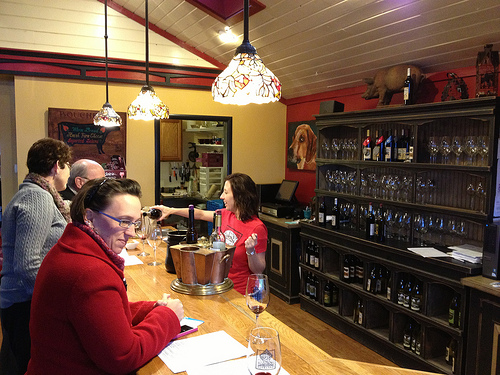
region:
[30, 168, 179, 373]
Woman standing in front of bar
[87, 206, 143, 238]
Eyeglasses on the woman's face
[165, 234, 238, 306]
Bucket on the counter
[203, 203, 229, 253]
Bottle in the bucket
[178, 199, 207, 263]
Bottle in the bucket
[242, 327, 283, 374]
Wine glass on counter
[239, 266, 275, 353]
Wine glass on counter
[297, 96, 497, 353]
Shelf against the wall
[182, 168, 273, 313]
Woman wearing a red shirt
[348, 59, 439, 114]
Pig on top of shelf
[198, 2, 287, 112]
very decorative overhead lamp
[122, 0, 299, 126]
two decorative lamps hanging down from black poles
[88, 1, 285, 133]
three decorative lamps hanging from the ceiling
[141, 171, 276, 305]
bartender wearing a red t-shirt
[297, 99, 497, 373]
bar full of bottles and glasses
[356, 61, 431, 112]
wooden decorative pig with a liquor bottle in front of it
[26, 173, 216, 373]
woman wearing a red sweater and sitting at a bar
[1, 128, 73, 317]
woman wearing a blue sweater and a scarf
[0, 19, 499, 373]
bar with three patrons and a bartender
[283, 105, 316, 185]
picture of a dog against a red wall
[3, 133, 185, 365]
Three people at the bar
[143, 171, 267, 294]
Bartender pouring a drink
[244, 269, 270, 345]
Empty glass of wine on the bar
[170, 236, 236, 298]
Large silver ice bucket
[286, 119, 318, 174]
Picture of a dog on the wall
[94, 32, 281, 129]
Three lamps hanging from the ceiling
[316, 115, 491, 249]
Glasses on shelves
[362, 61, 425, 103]
Pig statue on top of shelf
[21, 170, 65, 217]
Scarf around woman's neck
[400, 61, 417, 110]
Bottle on top of shelf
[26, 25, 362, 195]
Three bar lamps hanging from ceiling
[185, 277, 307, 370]
Two wineglasses on bar counter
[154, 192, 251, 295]
Two wine bottles in a wine container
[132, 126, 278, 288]
Bartender pouring wine into a glass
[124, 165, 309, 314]
Woman pouring wine into a wineglass at bar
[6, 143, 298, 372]
Woman looking at paper on bar counter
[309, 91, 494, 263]
Many wine glasses and a few wine bottles at a bar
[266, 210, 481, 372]
Many wine bottles at a bar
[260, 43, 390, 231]
Painting of a dog at a bar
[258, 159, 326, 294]
Cash register at a bar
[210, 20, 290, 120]
patterned ceiling light shade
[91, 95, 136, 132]
patterned ceiling light shade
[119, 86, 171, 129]
patterned ceiling light shade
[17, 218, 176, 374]
woman wearing a red coat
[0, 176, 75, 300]
woman wearing a grey sweater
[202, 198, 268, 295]
woman wearing a red shirt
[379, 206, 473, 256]
wine glass on shelf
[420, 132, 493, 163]
wine glass on shelf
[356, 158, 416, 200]
wine glass on shelf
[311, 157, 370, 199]
wine glass on shelf